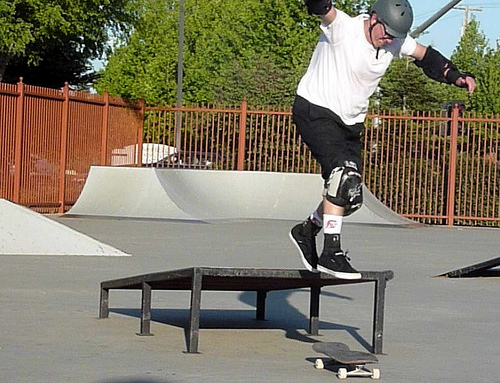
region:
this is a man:
[313, 3, 418, 271]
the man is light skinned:
[362, 20, 386, 49]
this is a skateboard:
[307, 330, 371, 380]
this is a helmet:
[380, 0, 412, 35]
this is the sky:
[431, 4, 459, 37]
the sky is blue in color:
[439, 26, 459, 37]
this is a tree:
[223, 14, 282, 86]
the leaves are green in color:
[229, 16, 274, 54]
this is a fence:
[411, 115, 497, 201]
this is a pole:
[176, 16, 187, 105]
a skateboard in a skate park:
[307, 332, 382, 382]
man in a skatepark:
[282, 2, 477, 281]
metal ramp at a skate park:
[93, 260, 400, 356]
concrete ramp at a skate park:
[82, 151, 413, 236]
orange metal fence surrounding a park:
[369, 112, 499, 223]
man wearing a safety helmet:
[366, 0, 417, 42]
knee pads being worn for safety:
[316, 155, 373, 216]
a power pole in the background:
[450, 0, 492, 37]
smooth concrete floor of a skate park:
[418, 304, 493, 376]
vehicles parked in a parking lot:
[135, 130, 230, 172]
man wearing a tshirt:
[290, 5, 426, 280]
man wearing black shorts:
[296, 6, 487, 281]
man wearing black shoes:
[275, 8, 382, 280]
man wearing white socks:
[262, 2, 377, 278]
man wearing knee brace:
[271, 5, 437, 275]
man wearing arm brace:
[277, 3, 482, 268]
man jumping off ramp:
[211, 6, 423, 326]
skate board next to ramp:
[291, 325, 391, 376]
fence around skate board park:
[412, 116, 478, 216]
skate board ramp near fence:
[78, 152, 241, 231]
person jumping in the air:
[293, 8, 478, 302]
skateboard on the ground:
[310, 338, 392, 381]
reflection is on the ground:
[241, 293, 346, 341]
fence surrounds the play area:
[128, 110, 485, 211]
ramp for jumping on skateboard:
[105, 269, 382, 349]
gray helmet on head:
[366, 4, 425, 34]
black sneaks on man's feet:
[277, 225, 365, 276]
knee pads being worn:
[331, 158, 358, 215]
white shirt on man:
[318, 38, 390, 118]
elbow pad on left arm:
[426, 52, 453, 87]